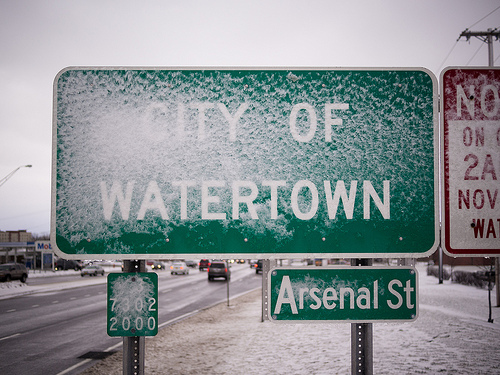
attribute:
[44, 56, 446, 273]
sign — green, snowy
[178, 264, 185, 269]
tail light — red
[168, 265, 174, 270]
tail light — red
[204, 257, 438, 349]
sign — snowy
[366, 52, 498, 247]
sign — street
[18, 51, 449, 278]
sign — snowy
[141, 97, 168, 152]
letter — C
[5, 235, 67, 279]
gas station — in background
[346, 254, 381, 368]
post — metal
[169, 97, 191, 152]
letter — I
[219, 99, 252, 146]
letter — Y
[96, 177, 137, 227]
letter — W